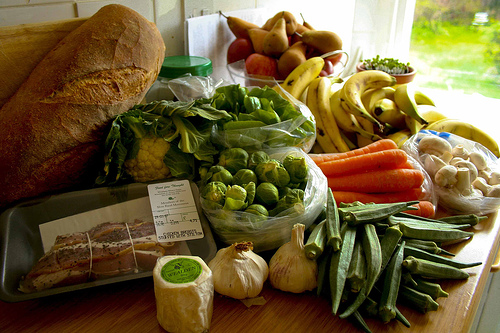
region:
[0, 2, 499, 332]
the food on the table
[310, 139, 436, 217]
the pile of carrots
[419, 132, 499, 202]
the pile of mushrooms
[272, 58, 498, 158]
the pile of bananas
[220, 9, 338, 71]
the pile of pears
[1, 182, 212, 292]
the meat on the black tray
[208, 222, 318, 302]
the two garlics on the table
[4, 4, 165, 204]
the loaf of bread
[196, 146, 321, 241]
the pile of brussel sprouts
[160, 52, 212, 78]
the green lid to a jar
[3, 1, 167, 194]
loaf of Italian bread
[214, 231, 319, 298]
two cloves of fresh garlic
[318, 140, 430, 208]
bunch of fresh bright orange carrots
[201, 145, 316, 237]
bag of fresh brussel sprouts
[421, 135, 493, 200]
bag of fresh mushrooms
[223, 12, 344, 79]
fresh pears and apples in a bowl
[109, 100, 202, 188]
fresh head of cauliflower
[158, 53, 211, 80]
green lid on jar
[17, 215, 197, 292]
stuffed tied pork roll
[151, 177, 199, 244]
market price tag on paskage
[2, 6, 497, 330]
food on wood table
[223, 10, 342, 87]
fruit in clear bowl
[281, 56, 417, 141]
pile of ripe bananas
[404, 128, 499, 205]
mushrooms in plastic bag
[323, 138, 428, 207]
sticks of raw carrots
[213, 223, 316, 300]
two cloves of garlic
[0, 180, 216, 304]
meat in plastic container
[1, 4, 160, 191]
loaf of bread standing upright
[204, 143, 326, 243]
brussel sprouts in bag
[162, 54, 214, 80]
green cover of jar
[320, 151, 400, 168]
carrot on the counter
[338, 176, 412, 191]
carrot on the counter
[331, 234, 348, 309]
okra on the counter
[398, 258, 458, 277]
okra on the counter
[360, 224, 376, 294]
okra on the counter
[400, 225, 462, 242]
okra on the counter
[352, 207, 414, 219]
okra on the counter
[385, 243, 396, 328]
okra on the counter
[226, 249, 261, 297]
clove of garlic on table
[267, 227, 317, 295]
clove of garlic on table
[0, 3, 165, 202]
Loaf of crusty bread on a table.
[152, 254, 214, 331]
Wrapped cheese on a table.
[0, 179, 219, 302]
Black styrofoam container on a table.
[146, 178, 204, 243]
Price and weight tag on product.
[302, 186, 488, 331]
Bunch of okra on a table.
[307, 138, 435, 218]
Orange carrots on a table.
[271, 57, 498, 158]
Yellow bananas on a table.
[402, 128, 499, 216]
Sack of mushrooms on a table.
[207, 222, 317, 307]
Pair of garlic bulbs on a table.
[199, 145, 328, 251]
Sack of brussels sprouts on a table.